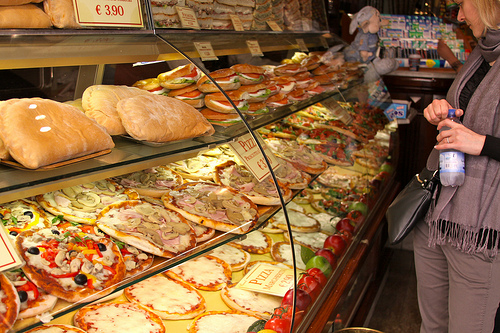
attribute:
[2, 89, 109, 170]
sandwich — large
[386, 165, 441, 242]
purse — black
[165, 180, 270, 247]
pizza — umbaked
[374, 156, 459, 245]
purse — black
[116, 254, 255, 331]
pizza — displayed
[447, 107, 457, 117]
cap — blue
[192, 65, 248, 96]
sandwich — large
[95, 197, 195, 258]
pizza — unbaked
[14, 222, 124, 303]
pizza — unbaked, cheese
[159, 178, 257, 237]
pizza — unbaked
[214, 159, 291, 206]
pizza — unbaked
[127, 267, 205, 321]
pizza — unbaked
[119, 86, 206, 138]
sandwich — large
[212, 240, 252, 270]
pizza — unbaked, cheese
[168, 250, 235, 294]
pizza — unbaked, cheese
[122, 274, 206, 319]
pizza — unbaked, cheese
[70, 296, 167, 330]
pizza — unbaked, cheese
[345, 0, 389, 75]
doll — stuffed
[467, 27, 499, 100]
scarf/woman's neck — Gray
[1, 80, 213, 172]
calzones — unbaked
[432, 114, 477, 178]
bottle — water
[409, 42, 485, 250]
scarf — gray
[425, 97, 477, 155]
hands — woman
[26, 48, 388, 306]
case — display